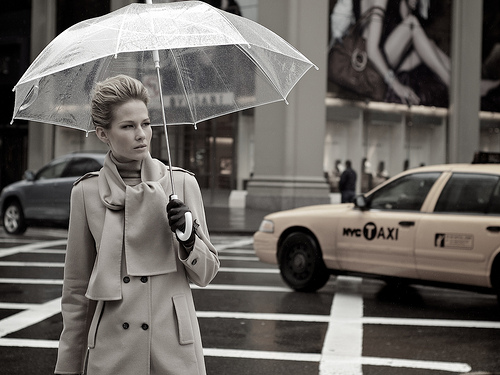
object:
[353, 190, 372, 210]
rearview mirror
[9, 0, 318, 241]
umbrella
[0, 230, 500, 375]
crosswalk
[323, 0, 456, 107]
picture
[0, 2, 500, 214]
building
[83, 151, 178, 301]
scarf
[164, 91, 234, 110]
writing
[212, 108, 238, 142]
window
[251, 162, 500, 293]
car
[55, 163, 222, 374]
coat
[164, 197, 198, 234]
hand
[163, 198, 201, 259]
glove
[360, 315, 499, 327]
lines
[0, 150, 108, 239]
vehicle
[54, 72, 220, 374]
woman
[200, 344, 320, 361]
line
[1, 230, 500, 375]
road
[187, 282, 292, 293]
line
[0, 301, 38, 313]
line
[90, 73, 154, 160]
head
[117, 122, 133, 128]
eye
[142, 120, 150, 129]
eye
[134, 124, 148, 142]
nose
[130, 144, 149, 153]
lips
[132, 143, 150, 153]
mouth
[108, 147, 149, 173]
neck